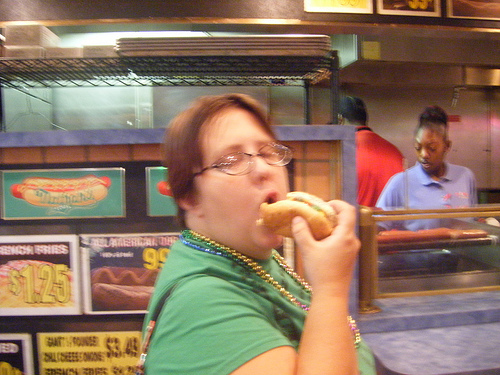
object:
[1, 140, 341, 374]
wall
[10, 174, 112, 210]
hot dog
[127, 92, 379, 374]
person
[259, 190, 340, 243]
hotdog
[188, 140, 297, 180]
eyeglasses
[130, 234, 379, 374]
shirt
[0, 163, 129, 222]
sign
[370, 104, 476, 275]
lady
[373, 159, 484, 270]
blue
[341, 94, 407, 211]
person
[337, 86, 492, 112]
back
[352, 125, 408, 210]
shirt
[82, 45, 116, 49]
sheets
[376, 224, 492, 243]
food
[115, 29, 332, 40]
trays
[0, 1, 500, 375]
restaurant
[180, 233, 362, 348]
beads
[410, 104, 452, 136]
hair up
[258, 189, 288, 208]
mouth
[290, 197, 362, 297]
hand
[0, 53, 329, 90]
shelf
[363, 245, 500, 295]
down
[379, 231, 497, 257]
grills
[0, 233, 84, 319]
sign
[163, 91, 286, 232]
short hair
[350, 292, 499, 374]
counter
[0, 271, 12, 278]
french fries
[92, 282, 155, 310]
hot dog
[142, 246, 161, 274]
one dollar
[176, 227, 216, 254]
colors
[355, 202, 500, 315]
partition